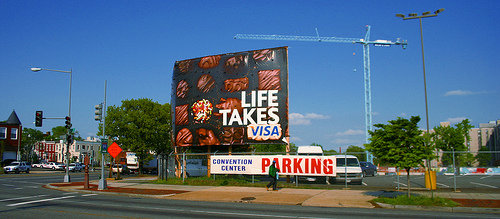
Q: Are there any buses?
A: No, there are no buses.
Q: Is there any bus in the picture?
A: No, there are no buses.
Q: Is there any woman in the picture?
A: No, there are no women.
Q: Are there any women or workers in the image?
A: No, there are no women or workers.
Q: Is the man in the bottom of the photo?
A: Yes, the man is in the bottom of the image.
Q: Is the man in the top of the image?
A: No, the man is in the bottom of the image.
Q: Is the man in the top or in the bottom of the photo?
A: The man is in the bottom of the image.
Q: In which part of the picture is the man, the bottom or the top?
A: The man is in the bottom of the image.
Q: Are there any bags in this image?
A: No, there are no bags.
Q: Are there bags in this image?
A: No, there are no bags.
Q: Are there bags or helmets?
A: No, there are no bags or helmets.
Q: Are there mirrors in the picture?
A: No, there are no mirrors.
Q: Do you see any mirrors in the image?
A: No, there are no mirrors.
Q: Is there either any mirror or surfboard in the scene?
A: No, there are no mirrors or surfboards.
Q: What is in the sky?
A: The clouds are in the sky.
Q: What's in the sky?
A: The clouds are in the sky.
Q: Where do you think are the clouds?
A: The clouds are in the sky.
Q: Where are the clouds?
A: The clouds are in the sky.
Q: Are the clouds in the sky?
A: Yes, the clouds are in the sky.